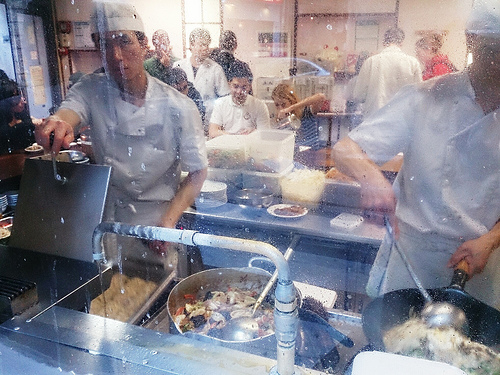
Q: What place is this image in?
A: It is at the restaurant.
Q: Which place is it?
A: It is a restaurant.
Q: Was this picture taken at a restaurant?
A: Yes, it was taken in a restaurant.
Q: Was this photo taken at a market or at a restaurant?
A: It was taken at a restaurant.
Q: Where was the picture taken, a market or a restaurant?
A: It was taken at a restaurant.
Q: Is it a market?
A: No, it is a restaurant.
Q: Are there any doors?
A: Yes, there is a door.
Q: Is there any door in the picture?
A: Yes, there is a door.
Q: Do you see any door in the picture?
A: Yes, there is a door.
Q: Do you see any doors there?
A: Yes, there is a door.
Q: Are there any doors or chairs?
A: Yes, there is a door.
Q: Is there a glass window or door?
A: Yes, there is a glass door.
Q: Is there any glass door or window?
A: Yes, there is a glass door.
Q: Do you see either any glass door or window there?
A: Yes, there is a glass door.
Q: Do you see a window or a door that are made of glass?
A: Yes, the door is made of glass.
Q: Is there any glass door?
A: Yes, there is a door that is made of glass.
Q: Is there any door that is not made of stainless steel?
A: Yes, there is a door that is made of glass.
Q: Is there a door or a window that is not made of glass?
A: No, there is a door but it is made of glass.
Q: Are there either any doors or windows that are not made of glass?
A: No, there is a door but it is made of glass.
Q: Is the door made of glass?
A: Yes, the door is made of glass.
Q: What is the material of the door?
A: The door is made of glass.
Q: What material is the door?
A: The door is made of glass.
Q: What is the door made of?
A: The door is made of glass.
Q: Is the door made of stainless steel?
A: No, the door is made of glass.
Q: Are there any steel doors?
A: No, there is a door but it is made of glass.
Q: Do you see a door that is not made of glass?
A: No, there is a door but it is made of glass.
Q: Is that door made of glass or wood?
A: The door is made of glass.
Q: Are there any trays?
A: No, there are no trays.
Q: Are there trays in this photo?
A: No, there are no trays.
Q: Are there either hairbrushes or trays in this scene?
A: No, there are no trays or hairbrushes.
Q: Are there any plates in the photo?
A: Yes, there is a plate.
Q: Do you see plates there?
A: Yes, there is a plate.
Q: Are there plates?
A: Yes, there is a plate.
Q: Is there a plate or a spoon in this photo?
A: Yes, there is a plate.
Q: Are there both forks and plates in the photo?
A: No, there is a plate but no forks.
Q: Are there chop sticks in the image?
A: No, there are no chop sticks.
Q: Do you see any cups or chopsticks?
A: No, there are no chopsticks or cups.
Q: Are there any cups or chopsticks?
A: No, there are no chopsticks or cups.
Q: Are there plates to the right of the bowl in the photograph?
A: Yes, there is a plate to the right of the bowl.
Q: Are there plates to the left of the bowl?
A: No, the plate is to the right of the bowl.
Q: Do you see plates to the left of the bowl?
A: No, the plate is to the right of the bowl.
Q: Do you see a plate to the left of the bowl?
A: No, the plate is to the right of the bowl.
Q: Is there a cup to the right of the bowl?
A: No, there is a plate to the right of the bowl.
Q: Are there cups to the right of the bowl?
A: No, there is a plate to the right of the bowl.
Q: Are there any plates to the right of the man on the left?
A: Yes, there is a plate to the right of the man.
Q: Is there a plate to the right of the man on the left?
A: Yes, there is a plate to the right of the man.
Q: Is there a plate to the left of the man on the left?
A: No, the plate is to the right of the man.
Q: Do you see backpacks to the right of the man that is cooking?
A: No, there is a plate to the right of the man.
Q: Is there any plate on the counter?
A: Yes, there is a plate on the counter.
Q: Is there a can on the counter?
A: No, there is a plate on the counter.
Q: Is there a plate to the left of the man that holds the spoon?
A: Yes, there is a plate to the left of the man.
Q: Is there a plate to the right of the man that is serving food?
A: No, the plate is to the left of the man.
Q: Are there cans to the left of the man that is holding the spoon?
A: No, there is a plate to the left of the man.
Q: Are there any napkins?
A: No, there are no napkins.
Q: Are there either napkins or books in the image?
A: No, there are no napkins or books.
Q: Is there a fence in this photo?
A: No, there are no fences.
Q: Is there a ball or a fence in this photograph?
A: No, there are no fences or balls.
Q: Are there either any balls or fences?
A: No, there are no fences or balls.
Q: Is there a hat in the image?
A: Yes, there is a hat.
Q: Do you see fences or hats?
A: Yes, there is a hat.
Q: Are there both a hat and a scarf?
A: No, there is a hat but no scarves.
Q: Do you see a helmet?
A: No, there are no helmets.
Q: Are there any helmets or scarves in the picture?
A: No, there are no helmets or scarves.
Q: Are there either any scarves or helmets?
A: No, there are no helmets or scarves.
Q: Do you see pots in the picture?
A: Yes, there is a pot.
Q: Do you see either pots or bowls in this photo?
A: Yes, there is a pot.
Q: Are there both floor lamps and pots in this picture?
A: No, there is a pot but no floor lamps.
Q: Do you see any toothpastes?
A: No, there are no toothpastes.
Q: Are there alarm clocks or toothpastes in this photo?
A: No, there are no toothpastes or alarm clocks.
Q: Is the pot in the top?
A: No, the pot is in the bottom of the image.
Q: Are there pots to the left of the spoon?
A: Yes, there is a pot to the left of the spoon.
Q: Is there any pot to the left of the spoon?
A: Yes, there is a pot to the left of the spoon.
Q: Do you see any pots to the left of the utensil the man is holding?
A: Yes, there is a pot to the left of the spoon.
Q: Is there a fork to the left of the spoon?
A: No, there is a pot to the left of the spoon.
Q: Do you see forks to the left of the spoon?
A: No, there is a pot to the left of the spoon.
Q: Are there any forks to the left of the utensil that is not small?
A: No, there is a pot to the left of the spoon.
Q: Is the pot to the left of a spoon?
A: Yes, the pot is to the left of a spoon.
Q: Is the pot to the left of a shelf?
A: No, the pot is to the left of a spoon.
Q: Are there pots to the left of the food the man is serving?
A: Yes, there is a pot to the left of the food.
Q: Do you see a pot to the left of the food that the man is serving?
A: Yes, there is a pot to the left of the food.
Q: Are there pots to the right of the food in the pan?
A: No, the pot is to the left of the food.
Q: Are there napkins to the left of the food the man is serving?
A: No, there is a pot to the left of the food.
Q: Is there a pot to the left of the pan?
A: Yes, there is a pot to the left of the pan.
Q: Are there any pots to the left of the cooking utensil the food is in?
A: Yes, there is a pot to the left of the pan.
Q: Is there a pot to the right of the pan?
A: No, the pot is to the left of the pan.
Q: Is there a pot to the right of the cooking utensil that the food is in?
A: No, the pot is to the left of the pan.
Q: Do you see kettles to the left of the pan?
A: No, there is a pot to the left of the pan.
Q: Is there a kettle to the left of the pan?
A: No, there is a pot to the left of the pan.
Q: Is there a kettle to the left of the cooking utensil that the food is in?
A: No, there is a pot to the left of the pan.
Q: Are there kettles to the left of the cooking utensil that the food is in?
A: No, there is a pot to the left of the pan.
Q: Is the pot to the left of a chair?
A: No, the pot is to the left of a pan.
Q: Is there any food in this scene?
A: Yes, there is food.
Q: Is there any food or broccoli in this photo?
A: Yes, there is food.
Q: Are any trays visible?
A: No, there are no trays.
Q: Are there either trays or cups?
A: No, there are no trays or cups.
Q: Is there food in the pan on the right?
A: Yes, there is food in the pan.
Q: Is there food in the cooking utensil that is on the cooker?
A: Yes, there is food in the pan.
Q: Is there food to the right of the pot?
A: Yes, there is food to the right of the pot.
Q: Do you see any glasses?
A: No, there are no glasses.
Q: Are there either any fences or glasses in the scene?
A: No, there are no glasses or fences.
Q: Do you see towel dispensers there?
A: No, there are no towel dispensers.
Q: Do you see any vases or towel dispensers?
A: No, there are no towel dispensers or vases.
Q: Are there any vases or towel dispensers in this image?
A: No, there are no towel dispensers or vases.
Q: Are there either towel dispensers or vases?
A: No, there are no towel dispensers or vases.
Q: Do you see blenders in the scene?
A: No, there are no blenders.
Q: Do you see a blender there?
A: No, there are no blenders.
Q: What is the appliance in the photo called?
A: The appliance is a cooker.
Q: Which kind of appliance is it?
A: The appliance is a cooker.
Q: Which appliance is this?
A: That is a cooker.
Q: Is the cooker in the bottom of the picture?
A: Yes, the cooker is in the bottom of the image.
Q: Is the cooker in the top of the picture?
A: No, the cooker is in the bottom of the image.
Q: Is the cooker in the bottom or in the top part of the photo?
A: The cooker is in the bottom of the image.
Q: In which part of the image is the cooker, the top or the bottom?
A: The cooker is in the bottom of the image.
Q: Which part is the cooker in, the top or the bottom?
A: The cooker is in the bottom of the image.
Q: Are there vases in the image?
A: No, there are no vases.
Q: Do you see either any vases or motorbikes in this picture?
A: No, there are no vases or motorbikes.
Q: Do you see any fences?
A: No, there are no fences.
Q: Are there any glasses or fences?
A: No, there are no fences or glasses.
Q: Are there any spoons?
A: Yes, there is a spoon.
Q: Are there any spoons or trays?
A: Yes, there is a spoon.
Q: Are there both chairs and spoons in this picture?
A: No, there is a spoon but no chairs.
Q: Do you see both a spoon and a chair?
A: No, there is a spoon but no chairs.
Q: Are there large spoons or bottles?
A: Yes, there is a large spoon.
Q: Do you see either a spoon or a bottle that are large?
A: Yes, the spoon is large.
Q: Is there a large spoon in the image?
A: Yes, there is a large spoon.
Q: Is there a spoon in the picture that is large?
A: Yes, there is a spoon that is large.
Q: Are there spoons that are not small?
A: Yes, there is a large spoon.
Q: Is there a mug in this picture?
A: No, there are no mugs.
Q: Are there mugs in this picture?
A: No, there are no mugs.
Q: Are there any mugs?
A: No, there are no mugs.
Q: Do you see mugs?
A: No, there are no mugs.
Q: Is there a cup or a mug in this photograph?
A: No, there are no mugs or cups.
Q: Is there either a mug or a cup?
A: No, there are no mugs or cups.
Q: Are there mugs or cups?
A: No, there are no mugs or cups.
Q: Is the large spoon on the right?
A: Yes, the spoon is on the right of the image.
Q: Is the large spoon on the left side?
A: No, the spoon is on the right of the image.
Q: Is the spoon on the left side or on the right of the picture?
A: The spoon is on the right of the image.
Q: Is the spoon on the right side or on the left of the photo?
A: The spoon is on the right of the image.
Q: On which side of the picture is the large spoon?
A: The spoon is on the right of the image.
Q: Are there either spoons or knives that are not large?
A: No, there is a spoon but it is large.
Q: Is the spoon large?
A: Yes, the spoon is large.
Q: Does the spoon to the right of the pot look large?
A: Yes, the spoon is large.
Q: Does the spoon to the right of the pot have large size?
A: Yes, the spoon is large.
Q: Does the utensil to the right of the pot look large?
A: Yes, the spoon is large.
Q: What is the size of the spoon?
A: The spoon is large.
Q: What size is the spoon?
A: The spoon is large.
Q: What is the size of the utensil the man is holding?
A: The spoon is large.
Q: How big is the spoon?
A: The spoon is large.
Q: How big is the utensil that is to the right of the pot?
A: The spoon is large.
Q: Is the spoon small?
A: No, the spoon is large.